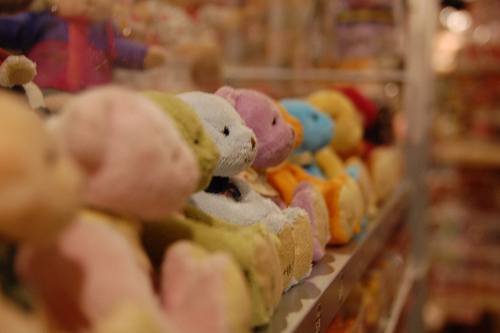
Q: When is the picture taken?
A: Daytime.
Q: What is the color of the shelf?
A: White.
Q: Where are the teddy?
A: In the shelf.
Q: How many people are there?
A: No one.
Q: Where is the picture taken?
A: At a toy store.